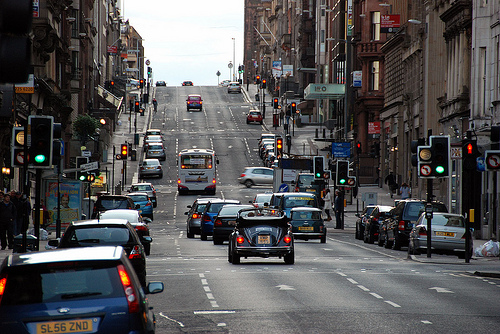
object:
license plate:
[31, 316, 108, 333]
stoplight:
[25, 114, 55, 166]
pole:
[34, 168, 41, 248]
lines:
[195, 267, 223, 309]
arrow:
[270, 282, 291, 293]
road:
[147, 102, 291, 237]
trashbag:
[475, 241, 497, 257]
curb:
[468, 243, 496, 262]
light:
[434, 165, 445, 174]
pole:
[425, 168, 434, 258]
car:
[227, 204, 292, 266]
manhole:
[193, 308, 237, 315]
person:
[383, 166, 404, 198]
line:
[190, 309, 231, 315]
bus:
[175, 149, 218, 194]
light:
[35, 155, 43, 164]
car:
[234, 166, 273, 187]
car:
[49, 220, 157, 289]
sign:
[416, 164, 433, 176]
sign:
[367, 116, 385, 134]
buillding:
[241, 0, 497, 246]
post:
[228, 80, 238, 132]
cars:
[173, 148, 218, 194]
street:
[156, 87, 472, 300]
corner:
[6, 0, 58, 254]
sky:
[113, 1, 246, 89]